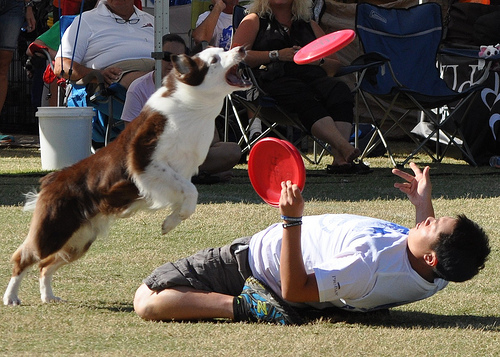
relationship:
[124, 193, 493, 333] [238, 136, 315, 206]
man holds frisbees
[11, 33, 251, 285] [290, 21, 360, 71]
dog chases frisbee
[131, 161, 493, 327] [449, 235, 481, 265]
man has hair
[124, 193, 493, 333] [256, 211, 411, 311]
man in shirt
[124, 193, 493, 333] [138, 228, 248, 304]
man wears shorts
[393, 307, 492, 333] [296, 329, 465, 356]
shadow on ground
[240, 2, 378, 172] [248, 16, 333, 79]
woman wears shirt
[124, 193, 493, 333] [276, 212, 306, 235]
man wears bracelet